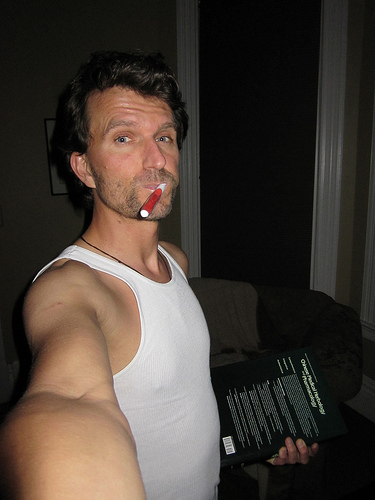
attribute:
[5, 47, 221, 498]
man — standing, posing, brushing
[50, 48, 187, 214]
hair — dark, brown, wavy, groomed, presentable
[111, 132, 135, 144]
eye — green, open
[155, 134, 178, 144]
eye — green, open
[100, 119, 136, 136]
eyebrow — brown, arched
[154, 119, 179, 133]
eyebrow — brown, arched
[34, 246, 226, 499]
shirt — white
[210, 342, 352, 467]
book — black, hardback